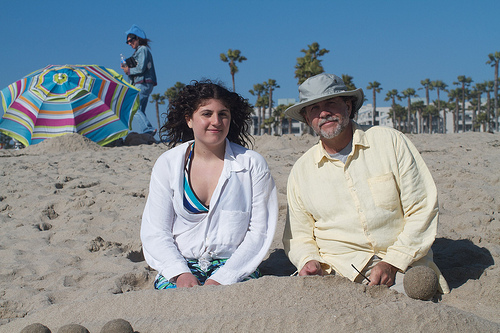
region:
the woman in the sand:
[140, 73, 287, 282]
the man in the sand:
[284, 72, 445, 309]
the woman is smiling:
[130, 70, 275, 182]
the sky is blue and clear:
[15, 2, 496, 53]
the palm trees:
[359, 45, 499, 125]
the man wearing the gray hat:
[267, 65, 392, 128]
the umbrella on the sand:
[0, 49, 139, 155]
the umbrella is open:
[5, 58, 150, 148]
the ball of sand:
[387, 261, 446, 302]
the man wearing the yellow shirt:
[292, 124, 454, 286]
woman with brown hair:
[151, 75, 263, 144]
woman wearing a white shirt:
[147, 128, 264, 273]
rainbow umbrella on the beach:
[10, 58, 140, 143]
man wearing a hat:
[284, 66, 359, 118]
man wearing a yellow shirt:
[297, 170, 417, 248]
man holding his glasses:
[349, 255, 386, 290]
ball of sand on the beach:
[397, 266, 450, 308]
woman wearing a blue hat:
[122, 25, 156, 47]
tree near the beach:
[282, 33, 324, 126]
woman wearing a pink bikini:
[176, 168, 217, 221]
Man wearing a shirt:
[287, 125, 444, 282]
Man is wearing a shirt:
[284, 121, 447, 280]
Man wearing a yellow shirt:
[281, 124, 447, 279]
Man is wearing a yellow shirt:
[280, 122, 440, 283]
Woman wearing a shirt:
[133, 135, 275, 286]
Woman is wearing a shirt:
[138, 135, 278, 292]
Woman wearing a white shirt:
[136, 135, 288, 286]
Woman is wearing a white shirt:
[135, 137, 278, 287]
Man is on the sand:
[280, 63, 457, 297]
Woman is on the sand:
[135, 70, 283, 288]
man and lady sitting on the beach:
[133, 67, 487, 302]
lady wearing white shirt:
[144, 82, 278, 289]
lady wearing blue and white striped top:
[147, 118, 255, 235]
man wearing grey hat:
[253, 61, 404, 147]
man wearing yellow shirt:
[275, 138, 487, 280]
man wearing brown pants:
[302, 205, 456, 307]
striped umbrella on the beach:
[3, 58, 154, 157]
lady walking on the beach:
[113, 27, 178, 119]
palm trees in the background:
[218, 39, 498, 139]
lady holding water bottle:
[110, 46, 170, 96]